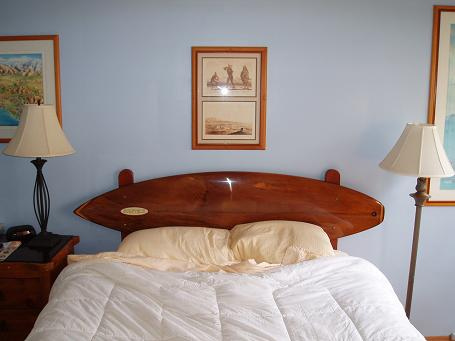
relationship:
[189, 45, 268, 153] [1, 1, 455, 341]
picture hanging on wall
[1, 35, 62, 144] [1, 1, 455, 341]
picture hanging on wall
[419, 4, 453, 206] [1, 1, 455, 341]
picture hanging on wall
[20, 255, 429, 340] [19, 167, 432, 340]
comforter on top of bed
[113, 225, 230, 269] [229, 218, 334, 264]
pillow lying next to pillow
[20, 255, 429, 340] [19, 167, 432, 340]
comforter laying on bed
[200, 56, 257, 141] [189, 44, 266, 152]
artwork inside of frame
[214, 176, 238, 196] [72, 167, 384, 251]
light reflection on front of headboard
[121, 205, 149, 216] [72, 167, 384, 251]
sticker on front of headboard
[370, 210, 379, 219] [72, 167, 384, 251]
circle on headboard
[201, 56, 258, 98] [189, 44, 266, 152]
picture inside of frame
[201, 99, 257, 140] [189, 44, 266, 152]
picture inside of frame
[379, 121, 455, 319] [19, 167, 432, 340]
floor lamp to right of bed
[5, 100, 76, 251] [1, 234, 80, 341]
lamp on top of nightstand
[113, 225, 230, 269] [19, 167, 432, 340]
pillow on top of bed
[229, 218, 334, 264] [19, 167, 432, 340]
pillow on top of bed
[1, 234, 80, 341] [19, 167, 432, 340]
nightstand to left of bed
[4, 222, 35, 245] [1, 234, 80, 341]
alarm clock on top of nightstand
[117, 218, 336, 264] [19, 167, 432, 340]
pillows on top of bed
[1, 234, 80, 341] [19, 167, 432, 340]
nightstand beside bed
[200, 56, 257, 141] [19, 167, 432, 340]
artwork above bed